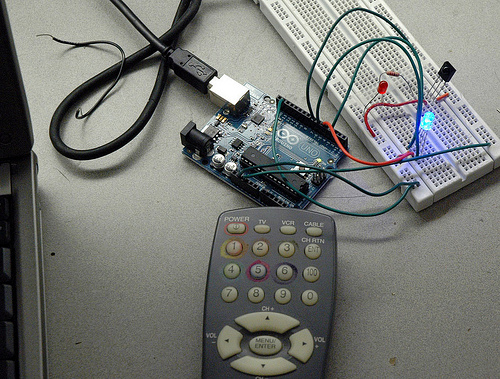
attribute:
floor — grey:
[57, 235, 177, 376]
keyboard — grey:
[215, 223, 320, 376]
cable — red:
[362, 101, 411, 140]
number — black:
[228, 239, 239, 251]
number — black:
[279, 261, 290, 281]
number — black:
[252, 287, 257, 294]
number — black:
[303, 289, 317, 303]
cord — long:
[62, 50, 198, 207]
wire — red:
[350, 79, 400, 146]